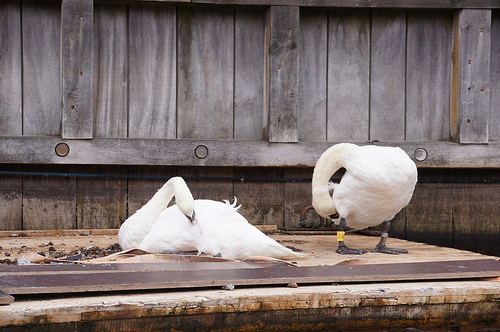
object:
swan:
[114, 175, 311, 264]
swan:
[307, 139, 422, 254]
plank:
[235, 9, 269, 143]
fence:
[0, 0, 500, 168]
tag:
[337, 232, 345, 242]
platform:
[0, 229, 500, 332]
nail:
[467, 86, 470, 92]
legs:
[334, 220, 343, 249]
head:
[312, 191, 343, 225]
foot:
[333, 245, 368, 255]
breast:
[334, 146, 418, 222]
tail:
[326, 179, 337, 193]